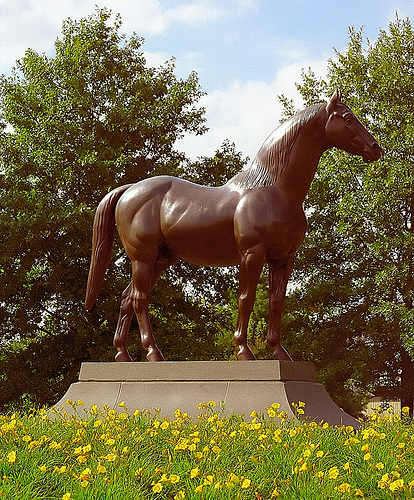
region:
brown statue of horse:
[63, 80, 390, 382]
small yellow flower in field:
[162, 469, 182, 488]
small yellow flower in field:
[240, 475, 250, 494]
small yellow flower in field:
[293, 398, 310, 419]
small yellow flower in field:
[269, 398, 283, 412]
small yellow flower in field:
[252, 414, 263, 431]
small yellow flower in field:
[302, 443, 315, 462]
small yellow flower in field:
[114, 397, 130, 410]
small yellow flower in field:
[205, 396, 218, 409]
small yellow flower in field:
[336, 478, 355, 496]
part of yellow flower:
[366, 406, 367, 436]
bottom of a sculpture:
[193, 361, 223, 375]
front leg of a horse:
[241, 303, 245, 315]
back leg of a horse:
[141, 293, 142, 316]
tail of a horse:
[98, 278, 100, 285]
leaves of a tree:
[334, 338, 360, 371]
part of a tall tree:
[55, 339, 63, 344]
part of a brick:
[240, 357, 254, 383]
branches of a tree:
[369, 295, 390, 306]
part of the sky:
[233, 65, 289, 109]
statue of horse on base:
[72, 86, 383, 377]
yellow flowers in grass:
[137, 418, 275, 484]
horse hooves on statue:
[103, 336, 295, 371]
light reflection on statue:
[225, 175, 261, 221]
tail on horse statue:
[69, 180, 130, 327]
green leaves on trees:
[59, 55, 142, 137]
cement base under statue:
[52, 350, 350, 443]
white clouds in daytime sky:
[225, 52, 311, 119]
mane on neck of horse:
[259, 119, 303, 197]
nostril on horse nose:
[367, 138, 387, 157]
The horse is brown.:
[75, 83, 382, 376]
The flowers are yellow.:
[1, 389, 412, 498]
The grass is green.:
[1, 395, 412, 496]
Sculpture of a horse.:
[57, 88, 386, 389]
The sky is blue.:
[1, 0, 412, 136]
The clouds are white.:
[2, 1, 332, 163]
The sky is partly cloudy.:
[1, 1, 412, 160]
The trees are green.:
[4, 5, 412, 312]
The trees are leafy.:
[2, 7, 413, 373]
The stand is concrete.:
[41, 351, 368, 450]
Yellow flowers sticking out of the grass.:
[87, 438, 276, 495]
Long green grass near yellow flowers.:
[94, 400, 276, 469]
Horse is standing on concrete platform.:
[75, 333, 331, 421]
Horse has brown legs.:
[97, 287, 285, 328]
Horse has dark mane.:
[259, 128, 310, 169]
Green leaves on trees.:
[330, 49, 407, 110]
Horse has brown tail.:
[74, 260, 148, 334]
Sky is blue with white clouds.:
[185, 14, 334, 96]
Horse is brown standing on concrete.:
[70, 188, 348, 256]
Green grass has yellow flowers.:
[102, 416, 361, 486]